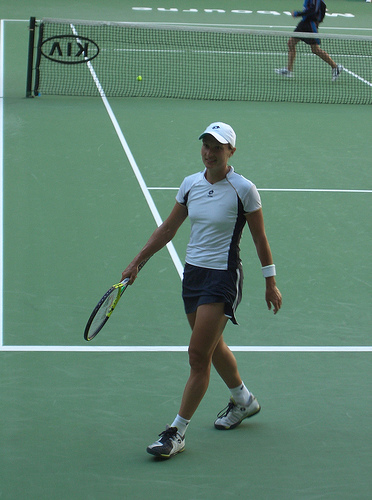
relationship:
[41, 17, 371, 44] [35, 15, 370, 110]
border of net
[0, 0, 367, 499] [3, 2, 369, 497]
court has floor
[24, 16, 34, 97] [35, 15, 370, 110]
pole of net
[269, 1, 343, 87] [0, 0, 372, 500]
tennis player on court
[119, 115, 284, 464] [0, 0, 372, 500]
tennis player on court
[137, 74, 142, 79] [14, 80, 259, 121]
ball on floor